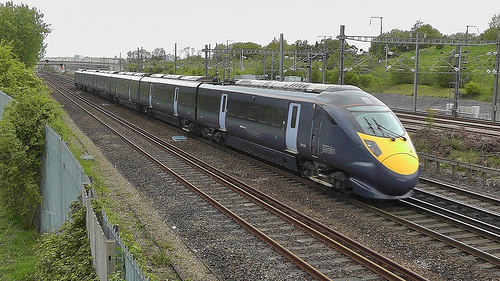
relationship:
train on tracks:
[76, 66, 419, 203] [40, 66, 499, 280]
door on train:
[284, 103, 306, 159] [76, 66, 419, 203]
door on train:
[217, 93, 232, 130] [76, 66, 419, 203]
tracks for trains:
[40, 66, 499, 280] [76, 66, 419, 203]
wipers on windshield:
[366, 116, 403, 144] [346, 105, 414, 144]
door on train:
[172, 86, 184, 120] [76, 66, 419, 203]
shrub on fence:
[1, 97, 45, 224] [1, 87, 152, 279]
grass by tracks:
[74, 145, 120, 189] [40, 66, 499, 280]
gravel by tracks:
[112, 201, 223, 278] [40, 66, 499, 280]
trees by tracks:
[0, 0, 59, 110] [40, 66, 499, 280]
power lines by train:
[73, 22, 495, 117] [76, 66, 419, 203]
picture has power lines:
[0, 1, 499, 278] [73, 22, 495, 117]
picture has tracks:
[0, 1, 499, 278] [40, 66, 499, 280]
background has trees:
[2, 4, 499, 115] [125, 23, 498, 72]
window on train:
[271, 107, 288, 131] [76, 66, 419, 203]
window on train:
[225, 100, 237, 118] [76, 66, 419, 203]